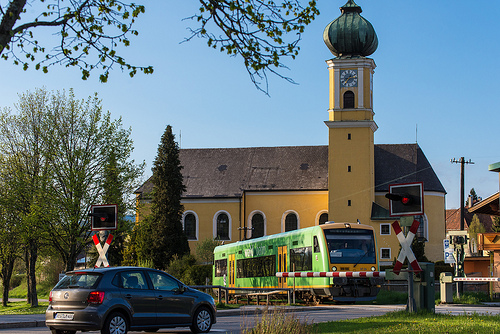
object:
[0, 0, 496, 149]
sky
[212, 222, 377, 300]
train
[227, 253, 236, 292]
door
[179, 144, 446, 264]
building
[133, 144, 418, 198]
roof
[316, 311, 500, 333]
grass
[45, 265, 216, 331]
car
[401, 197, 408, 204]
light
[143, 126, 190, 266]
trees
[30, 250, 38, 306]
trunk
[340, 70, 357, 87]
clock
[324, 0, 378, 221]
tower